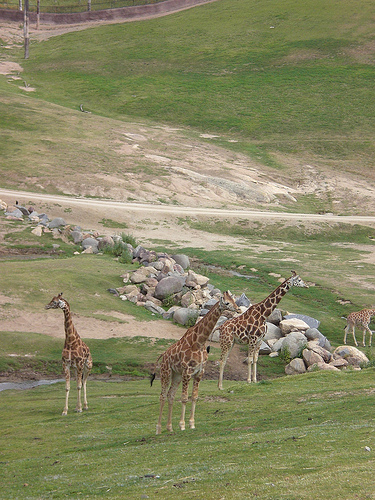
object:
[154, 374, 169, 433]
leg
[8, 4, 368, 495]
green grass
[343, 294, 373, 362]
giraffe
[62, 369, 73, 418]
white leg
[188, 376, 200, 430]
leg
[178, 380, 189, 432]
leg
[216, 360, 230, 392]
leg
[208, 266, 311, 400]
giraffe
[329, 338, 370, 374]
rocks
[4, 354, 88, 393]
water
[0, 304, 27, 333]
sand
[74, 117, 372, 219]
dirt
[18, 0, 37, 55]
tree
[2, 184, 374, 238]
roadway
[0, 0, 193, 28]
wall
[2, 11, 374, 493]
area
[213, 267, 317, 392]
animal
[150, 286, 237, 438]
animal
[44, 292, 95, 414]
animal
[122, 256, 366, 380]
stone pile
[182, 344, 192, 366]
spots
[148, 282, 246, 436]
african giraffe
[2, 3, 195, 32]
fence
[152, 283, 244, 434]
giraffe